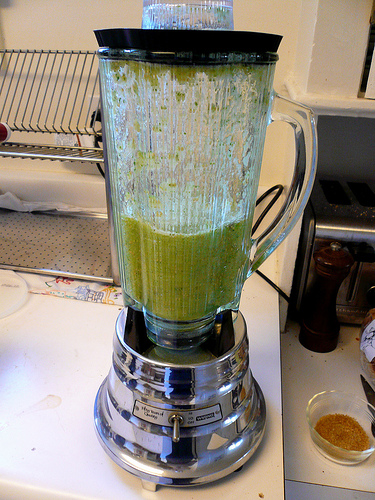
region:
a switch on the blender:
[167, 410, 190, 444]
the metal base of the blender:
[84, 300, 268, 494]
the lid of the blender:
[88, 1, 284, 66]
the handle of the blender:
[245, 89, 320, 276]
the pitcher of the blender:
[91, 1, 320, 358]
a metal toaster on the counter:
[288, 167, 374, 330]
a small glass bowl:
[301, 386, 373, 467]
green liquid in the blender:
[117, 212, 253, 323]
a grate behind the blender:
[0, 47, 108, 164]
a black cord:
[250, 180, 301, 316]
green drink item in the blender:
[117, 208, 246, 308]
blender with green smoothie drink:
[87, 4, 324, 320]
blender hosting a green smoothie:
[90, 0, 323, 491]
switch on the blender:
[172, 415, 178, 439]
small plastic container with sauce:
[308, 384, 373, 467]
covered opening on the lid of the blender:
[141, 4, 226, 30]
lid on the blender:
[94, 0, 285, 63]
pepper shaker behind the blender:
[288, 241, 356, 353]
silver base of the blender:
[90, 307, 264, 483]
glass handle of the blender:
[249, 94, 320, 276]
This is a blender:
[113, 133, 205, 388]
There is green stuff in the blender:
[84, 192, 258, 332]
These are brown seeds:
[319, 361, 360, 491]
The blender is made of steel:
[124, 322, 242, 458]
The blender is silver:
[106, 355, 242, 466]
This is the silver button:
[121, 407, 239, 447]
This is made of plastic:
[236, 135, 317, 252]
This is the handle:
[289, 116, 309, 227]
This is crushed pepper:
[298, 243, 370, 412]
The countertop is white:
[44, 415, 113, 487]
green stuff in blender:
[122, 186, 269, 283]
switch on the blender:
[151, 404, 199, 454]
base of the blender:
[140, 395, 291, 498]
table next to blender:
[6, 386, 77, 437]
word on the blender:
[187, 397, 226, 431]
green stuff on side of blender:
[113, 67, 245, 176]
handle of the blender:
[249, 88, 341, 262]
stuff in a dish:
[300, 390, 371, 475]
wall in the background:
[30, 14, 91, 47]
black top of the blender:
[79, 7, 310, 101]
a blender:
[114, 120, 247, 311]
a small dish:
[303, 409, 316, 429]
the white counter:
[28, 346, 86, 396]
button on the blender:
[167, 422, 189, 447]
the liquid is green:
[142, 234, 220, 295]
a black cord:
[265, 271, 286, 297]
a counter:
[291, 355, 329, 384]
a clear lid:
[6, 278, 29, 316]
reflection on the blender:
[159, 351, 218, 382]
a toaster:
[330, 209, 360, 237]